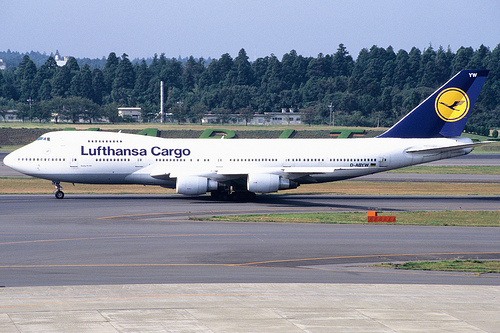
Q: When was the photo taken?
A: Daytime.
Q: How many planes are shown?
A: One.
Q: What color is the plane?
A: White.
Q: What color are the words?
A: Blue.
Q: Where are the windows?
A: Side of the plane.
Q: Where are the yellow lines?
A: Runway.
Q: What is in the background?
A: Trees.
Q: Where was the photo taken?
A: At an airport.